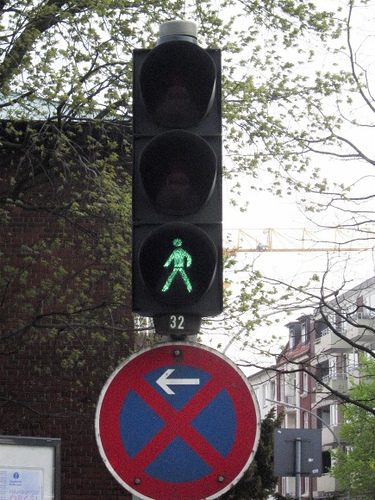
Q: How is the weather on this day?
A: It is clear.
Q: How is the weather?
A: It is clear.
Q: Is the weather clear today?
A: Yes, it is clear.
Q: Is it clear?
A: Yes, it is clear.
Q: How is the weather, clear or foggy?
A: It is clear.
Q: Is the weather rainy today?
A: No, it is clear.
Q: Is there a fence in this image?
A: No, there are no fences.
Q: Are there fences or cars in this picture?
A: No, there are no fences or cars.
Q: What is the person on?
A: The person is on the sign.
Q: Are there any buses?
A: No, there are no buses.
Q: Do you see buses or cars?
A: No, there are no buses or cars.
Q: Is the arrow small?
A: Yes, the arrow is small.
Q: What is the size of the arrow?
A: The arrow is small.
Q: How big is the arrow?
A: The arrow is small.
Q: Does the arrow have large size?
A: No, the arrow is small.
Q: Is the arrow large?
A: No, the arrow is small.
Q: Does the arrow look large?
A: No, the arrow is small.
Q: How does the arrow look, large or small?
A: The arrow is small.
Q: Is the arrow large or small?
A: The arrow is small.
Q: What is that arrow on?
A: The arrow is on the sign.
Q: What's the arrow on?
A: The arrow is on the sign.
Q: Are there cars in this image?
A: No, there are no cars.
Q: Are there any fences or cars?
A: No, there are no cars or fences.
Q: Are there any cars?
A: No, there are no cars.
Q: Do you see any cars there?
A: No, there are no cars.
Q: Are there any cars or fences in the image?
A: No, there are no cars or fences.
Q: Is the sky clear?
A: Yes, the sky is clear.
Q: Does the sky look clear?
A: Yes, the sky is clear.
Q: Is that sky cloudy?
A: No, the sky is clear.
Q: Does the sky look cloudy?
A: No, the sky is clear.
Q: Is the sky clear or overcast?
A: The sky is clear.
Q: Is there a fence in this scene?
A: No, there are no fences.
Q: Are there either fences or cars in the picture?
A: No, there are no fences or cars.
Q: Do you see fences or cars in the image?
A: No, there are no fences or cars.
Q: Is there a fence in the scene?
A: No, there are no fences.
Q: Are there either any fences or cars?
A: No, there are no fences or cars.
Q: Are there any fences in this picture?
A: No, there are no fences.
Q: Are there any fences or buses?
A: No, there are no fences or buses.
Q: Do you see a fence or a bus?
A: No, there are no fences or buses.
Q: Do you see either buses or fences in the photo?
A: No, there are no fences or buses.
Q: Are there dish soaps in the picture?
A: No, there are no dish soaps.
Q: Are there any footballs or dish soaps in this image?
A: No, there are no dish soaps or footballs.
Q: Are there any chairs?
A: No, there are no chairs.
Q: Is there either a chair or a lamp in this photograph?
A: No, there are no chairs or lamps.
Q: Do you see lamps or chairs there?
A: No, there are no chairs or lamps.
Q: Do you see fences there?
A: No, there are no fences.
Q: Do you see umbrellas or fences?
A: No, there are no fences or umbrellas.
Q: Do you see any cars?
A: No, there are no cars.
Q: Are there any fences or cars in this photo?
A: No, there are no cars or fences.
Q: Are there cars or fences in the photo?
A: No, there are no cars or fences.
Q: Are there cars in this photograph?
A: No, there are no cars.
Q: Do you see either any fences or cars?
A: No, there are no cars or fences.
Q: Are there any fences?
A: No, there are no fences.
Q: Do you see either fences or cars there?
A: No, there are no fences or cars.